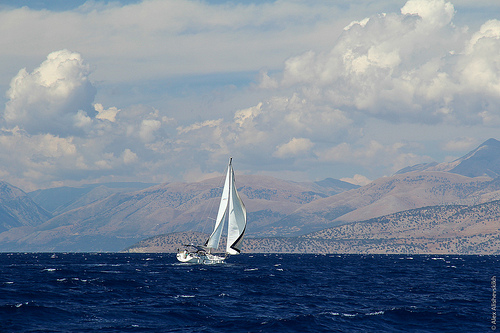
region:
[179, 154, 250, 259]
Sailboat on open water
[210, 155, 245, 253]
White sail on boat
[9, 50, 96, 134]
fat fluffy cloud in sky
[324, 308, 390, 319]
Whitecap on small wave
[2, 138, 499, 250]
Brown mountains beyond water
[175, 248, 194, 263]
White back of boat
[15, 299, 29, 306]
Tiny whitecap on wave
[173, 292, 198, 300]
Small whitecap on wave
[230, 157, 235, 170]
Metal tip on sailboat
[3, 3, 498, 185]
Large clouds covering sky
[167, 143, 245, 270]
white boat on blue ocean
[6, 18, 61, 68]
white clouds in blue sky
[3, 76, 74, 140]
white clouds in blue sky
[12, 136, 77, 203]
white clouds in blue sky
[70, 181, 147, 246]
white clouds in blue sky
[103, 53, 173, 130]
white clouds in blue sky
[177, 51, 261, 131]
white clouds in blue sky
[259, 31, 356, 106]
white clouds in blue sky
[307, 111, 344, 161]
white clouds in blue sky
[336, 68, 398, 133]
white clouds in blue sky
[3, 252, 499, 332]
A deep blue open sea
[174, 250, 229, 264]
A small white boat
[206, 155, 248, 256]
A large white sail on a boat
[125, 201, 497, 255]
A mountain covered with trees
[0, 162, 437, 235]
Tall mountains off in the distance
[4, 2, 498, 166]
A sky filled with clouds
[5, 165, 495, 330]
A small white boat out in the open sea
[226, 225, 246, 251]
A black lining on a sail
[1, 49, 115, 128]
A fluffy white cloud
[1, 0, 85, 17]
A small portion of the blue sky peeking through the clouds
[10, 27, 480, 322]
A sailboat is on the ocean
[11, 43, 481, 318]
A sailboat is carrying people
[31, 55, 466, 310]
People are sailing on a boat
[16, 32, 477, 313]
A boat is sailing somewhere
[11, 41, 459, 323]
The boat is powered by wind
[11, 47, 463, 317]
People are enjoying their day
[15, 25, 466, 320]
People are having some recreation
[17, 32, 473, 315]
People are enjoying the sunshine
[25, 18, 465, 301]
People are having some fun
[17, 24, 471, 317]
People are boating very safely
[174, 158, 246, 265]
White sailboat with tall white sails.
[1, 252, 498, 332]
Very dark blue water.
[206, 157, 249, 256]
White and black sails on a boat.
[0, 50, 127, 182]
Large puffy white clouds in the left sky.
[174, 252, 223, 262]
Body of a white boat.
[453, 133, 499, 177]
Dark peak on a right side tall mountain.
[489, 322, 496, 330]
Tiny copyright symbol.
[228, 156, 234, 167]
Small point above the white sails.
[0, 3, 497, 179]
All the blue and white cloudy sky.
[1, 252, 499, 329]
All of the dark blue water.